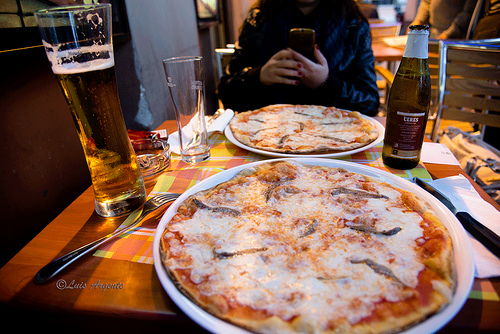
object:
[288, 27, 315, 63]
cell phone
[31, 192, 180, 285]
fork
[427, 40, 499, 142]
chair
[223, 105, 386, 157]
plate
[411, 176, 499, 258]
knife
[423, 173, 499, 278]
napkin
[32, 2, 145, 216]
glass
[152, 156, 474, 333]
serving plate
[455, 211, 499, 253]
handle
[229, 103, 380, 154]
pizza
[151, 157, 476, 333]
dish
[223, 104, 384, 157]
dish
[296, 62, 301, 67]
nail polish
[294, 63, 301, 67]
nail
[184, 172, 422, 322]
cheese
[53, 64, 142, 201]
beverage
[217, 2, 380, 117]
blue blouse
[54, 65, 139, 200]
beer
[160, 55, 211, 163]
beer glass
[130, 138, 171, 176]
ash tray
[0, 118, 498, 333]
table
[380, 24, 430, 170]
beer bottle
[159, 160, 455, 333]
pizza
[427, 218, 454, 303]
crust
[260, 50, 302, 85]
hand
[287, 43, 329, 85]
hand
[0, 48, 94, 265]
back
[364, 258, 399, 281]
anchovies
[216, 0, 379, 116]
lady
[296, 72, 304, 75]
polish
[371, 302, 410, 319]
orange sauce